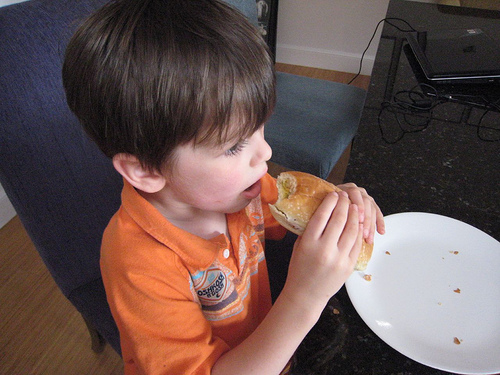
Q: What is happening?
A: The boy is eating.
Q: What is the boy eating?
A: A sandwich.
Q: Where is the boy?
A: At the counter.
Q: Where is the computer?
A: On the countertop.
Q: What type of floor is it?
A: Wood.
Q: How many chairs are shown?
A: Two.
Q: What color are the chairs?
A: Blue.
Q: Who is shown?
A: A boy.